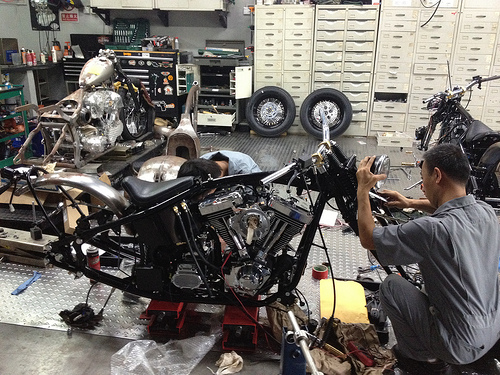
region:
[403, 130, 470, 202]
head of a person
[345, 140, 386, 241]
arm of a person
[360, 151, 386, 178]
hand of a person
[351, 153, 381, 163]
fingers of a person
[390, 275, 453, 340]
thigh of a person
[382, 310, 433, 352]
leg of a person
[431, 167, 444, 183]
ear of a person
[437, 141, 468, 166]
hair of a person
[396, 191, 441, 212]
arm of a person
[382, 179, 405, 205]
hand of a person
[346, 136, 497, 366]
MOTORCYCLE MECHANIC SQUATTED ON FLOOR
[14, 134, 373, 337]
PARTIALLY DISASSEMBLED MOTORCYCLE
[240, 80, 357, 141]
TWO TIRES LEANING AGAINST CABINETS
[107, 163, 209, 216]
SEAT OF MOTORCYCLE IS STILL ON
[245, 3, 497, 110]
CABINETS USED FOR STORING VARIOUS TOOLS AND PARTS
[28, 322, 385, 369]
MOTORCYCLE PARTS SCATTERED ON FLOOR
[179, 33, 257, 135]
TOOL CHEST AGAINST WALL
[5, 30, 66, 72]
SEVERAL BOTTLES SITTING ON SHELF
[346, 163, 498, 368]
MAN'S OUTFIT IS ONE PIECE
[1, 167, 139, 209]
REAR FENDER OF MOTORCYCLE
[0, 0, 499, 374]
the interior of a motorcycle shop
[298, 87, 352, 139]
a wheel on the floor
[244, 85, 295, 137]
a wheel on the floor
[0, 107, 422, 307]
a motorcycle being worked on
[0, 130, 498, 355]
a metal floor covering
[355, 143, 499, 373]
a mechanic working on the motorcycle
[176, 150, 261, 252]
a mechanic working on the motorcycle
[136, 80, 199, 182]
a motorcycle frame on the floor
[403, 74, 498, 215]
a motorcycle on the floor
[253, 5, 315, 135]
a large cabinet of drawers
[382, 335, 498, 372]
Man wearing shoes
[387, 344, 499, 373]
Man is wearing shoes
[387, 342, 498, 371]
Man wearing black shoes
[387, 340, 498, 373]
Man is wearing black shoes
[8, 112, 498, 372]
Man working on a motorcycle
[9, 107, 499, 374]
Man is working on a motorcycle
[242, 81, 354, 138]
Tires leaning against cabinet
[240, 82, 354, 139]
Tires are leaning against cabinets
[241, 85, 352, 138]
Black tires leaning against cabinet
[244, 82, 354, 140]
Black tires are leaning against cabinets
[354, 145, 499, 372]
man wearing gray overalls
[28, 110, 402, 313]
unarmed motorcycle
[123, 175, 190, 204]
black seat of unarmed motorcycle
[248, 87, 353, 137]
two black wheels besides white drawers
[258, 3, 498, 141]
white drawers on mechanical workshop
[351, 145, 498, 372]
mechanic working on motorcycle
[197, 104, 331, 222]
gray metal handle bar of unarmed motorcycle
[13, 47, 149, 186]
white unarmed motorcycle in the back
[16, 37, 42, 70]
red cans on the counter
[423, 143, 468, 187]
short black hair